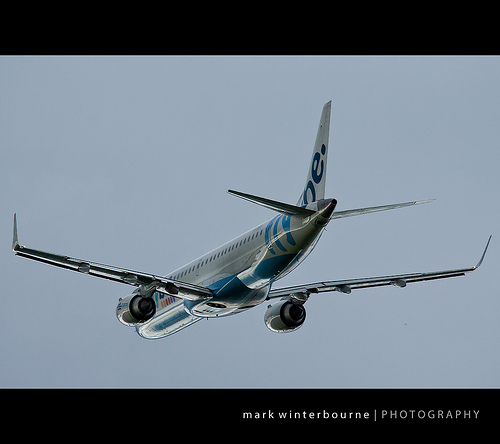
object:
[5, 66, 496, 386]
clouds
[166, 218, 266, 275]
windows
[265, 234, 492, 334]
right wing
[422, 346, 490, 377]
clouds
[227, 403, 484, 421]
text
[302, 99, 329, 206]
fin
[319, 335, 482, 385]
clouds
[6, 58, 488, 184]
sky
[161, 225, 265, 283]
windows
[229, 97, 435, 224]
tail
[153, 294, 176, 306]
row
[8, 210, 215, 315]
wing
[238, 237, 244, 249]
windows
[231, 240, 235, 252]
windows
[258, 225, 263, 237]
windows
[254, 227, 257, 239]
windows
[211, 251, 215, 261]
windows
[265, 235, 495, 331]
wing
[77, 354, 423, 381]
sky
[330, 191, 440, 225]
wing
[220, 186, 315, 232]
wing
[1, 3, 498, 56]
black bar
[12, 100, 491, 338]
plane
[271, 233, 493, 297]
wing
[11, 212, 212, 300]
wing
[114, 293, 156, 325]
engine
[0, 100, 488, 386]
jet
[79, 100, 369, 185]
clouds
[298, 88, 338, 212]
tail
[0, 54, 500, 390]
sky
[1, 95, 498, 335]
airplane